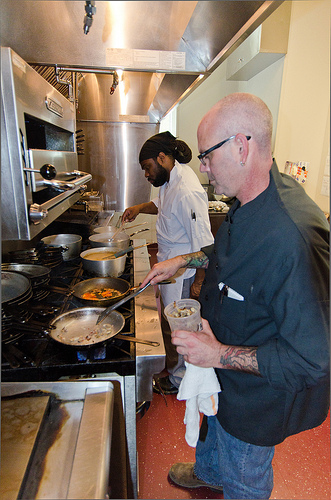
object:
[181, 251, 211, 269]
tattoo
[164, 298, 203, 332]
container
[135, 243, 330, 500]
floor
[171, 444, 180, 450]
spot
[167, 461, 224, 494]
shoe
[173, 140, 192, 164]
bun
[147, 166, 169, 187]
beard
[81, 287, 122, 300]
vegetables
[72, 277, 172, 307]
skillet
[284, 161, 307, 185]
dish cloth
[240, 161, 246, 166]
earring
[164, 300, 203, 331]
food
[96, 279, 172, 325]
spatula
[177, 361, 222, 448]
towel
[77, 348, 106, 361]
flames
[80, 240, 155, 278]
pot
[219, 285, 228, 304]
pen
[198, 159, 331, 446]
shirt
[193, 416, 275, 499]
jeans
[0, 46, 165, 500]
oven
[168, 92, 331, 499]
man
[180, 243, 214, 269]
arm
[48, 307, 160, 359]
pan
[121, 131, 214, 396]
man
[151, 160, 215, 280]
shirt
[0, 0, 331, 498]
kitchen